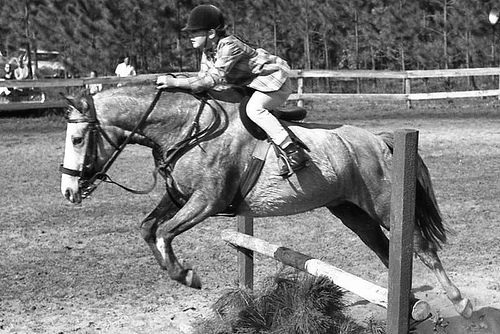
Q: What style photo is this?
A: Black and white.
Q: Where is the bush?
A: On wooden pole.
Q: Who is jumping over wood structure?
A: The horse.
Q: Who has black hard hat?
A: The girl.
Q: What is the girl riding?
A: The horse jumping.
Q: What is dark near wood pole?
A: Horse tail.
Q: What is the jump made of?
A: Wood.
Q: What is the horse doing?
A: Jumping.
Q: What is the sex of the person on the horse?
A: Female.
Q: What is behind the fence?
A: Trees.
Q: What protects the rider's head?
A: The helmet.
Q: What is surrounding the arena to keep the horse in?
A: A fence.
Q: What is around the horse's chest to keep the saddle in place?
A: A girth.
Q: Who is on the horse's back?
A: The girl rider.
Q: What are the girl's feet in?
A: Stirrups.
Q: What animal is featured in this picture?
A: A horse.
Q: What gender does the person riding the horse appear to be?
A: Female.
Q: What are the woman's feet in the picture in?
A: Stirrups.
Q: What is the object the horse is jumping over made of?
A: Wood.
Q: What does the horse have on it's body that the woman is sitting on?
A: A saddle.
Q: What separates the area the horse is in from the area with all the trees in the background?
A: A fence.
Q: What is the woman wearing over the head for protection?
A: A helmet.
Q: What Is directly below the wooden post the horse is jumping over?
A: A plant.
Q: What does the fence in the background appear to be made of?
A: Wood.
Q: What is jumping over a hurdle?
A: A horse.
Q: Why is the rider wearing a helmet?
A: To protect her head.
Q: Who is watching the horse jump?
A: The photographer.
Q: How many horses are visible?
A: One.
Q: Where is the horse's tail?
A: On the left, behind the hurdle.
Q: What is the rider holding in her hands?
A: The reins.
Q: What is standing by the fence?
A: Spectators, watching the jumping.